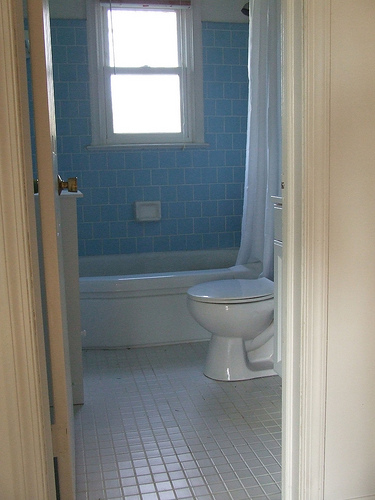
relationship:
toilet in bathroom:
[178, 268, 282, 390] [1, 10, 363, 498]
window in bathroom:
[94, 2, 195, 145] [15, 11, 347, 435]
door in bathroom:
[28, 1, 76, 499] [51, 0, 281, 498]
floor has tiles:
[73, 341, 284, 495] [78, 343, 278, 498]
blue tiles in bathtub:
[53, 19, 241, 249] [80, 245, 263, 347]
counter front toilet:
[24, 178, 88, 207] [185, 276, 280, 381]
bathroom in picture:
[25, 3, 298, 498] [1, 0, 369, 498]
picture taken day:
[109, 6, 182, 137] [111, 12, 177, 127]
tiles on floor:
[78, 343, 278, 498] [73, 341, 284, 495]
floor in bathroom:
[73, 341, 284, 495] [25, 3, 298, 498]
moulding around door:
[302, 69, 338, 293] [28, 1, 91, 498]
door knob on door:
[57, 174, 77, 196] [25, 3, 115, 493]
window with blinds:
[94, 2, 195, 145] [107, 7, 179, 73]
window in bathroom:
[78, 2, 217, 156] [25, 3, 283, 500]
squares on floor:
[138, 397, 244, 467] [73, 341, 284, 495]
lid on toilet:
[187, 274, 281, 308] [135, 230, 289, 391]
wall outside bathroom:
[276, 59, 367, 215] [25, 3, 298, 498]